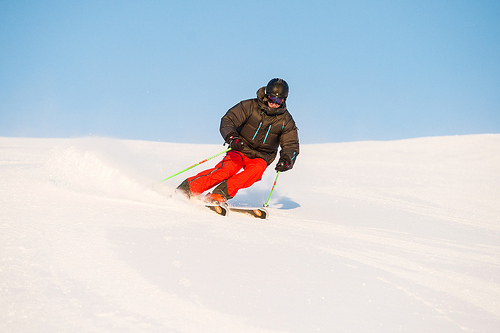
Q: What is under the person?
A: Snow.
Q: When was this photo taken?
A: Winter.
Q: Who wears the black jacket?
A: Skier.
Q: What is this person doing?
A: Skiing.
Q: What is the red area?
A: Ski pants.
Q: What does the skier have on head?
A: Helmet.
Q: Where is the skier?
A: On a slope.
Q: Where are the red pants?
A: Skier is wearing.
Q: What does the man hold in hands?
A: Ski poles.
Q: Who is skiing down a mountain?
A: The man.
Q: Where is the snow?
A: On the ground.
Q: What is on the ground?
A: Snow.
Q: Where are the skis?
A: On the man's feet.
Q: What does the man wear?
A: Brown jacket.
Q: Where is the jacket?
A: On the man.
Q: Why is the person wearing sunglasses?
A: It's bright.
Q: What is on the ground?
A: Snow.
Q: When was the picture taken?
A: Daytime.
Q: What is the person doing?
A: Skiing.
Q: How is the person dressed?
A: For cold weather.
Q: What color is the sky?
A: Blue.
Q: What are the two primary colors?
A: White and blue.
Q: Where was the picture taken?
A: A ski hill.